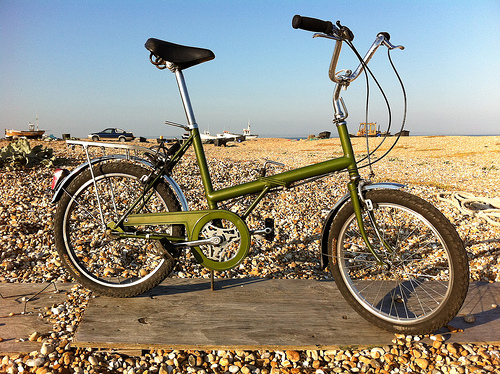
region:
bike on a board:
[51, 13, 461, 337]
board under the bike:
[68, 264, 479, 372]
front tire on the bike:
[308, 178, 467, 331]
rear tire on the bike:
[31, 158, 192, 288]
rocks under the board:
[138, 352, 225, 372]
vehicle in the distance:
[88, 122, 136, 142]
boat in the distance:
[3, 119, 49, 142]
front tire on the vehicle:
[88, 134, 100, 144]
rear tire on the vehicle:
[117, 135, 130, 142]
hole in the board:
[135, 311, 157, 328]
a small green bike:
[71, 26, 474, 320]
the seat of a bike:
[140, 37, 210, 82]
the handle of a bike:
[285, 7, 342, 42]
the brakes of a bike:
[366, 36, 414, 58]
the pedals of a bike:
[156, 231, 186, 266]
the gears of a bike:
[206, 217, 256, 268]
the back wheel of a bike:
[43, 146, 175, 281]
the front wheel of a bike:
[327, 195, 475, 330]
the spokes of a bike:
[390, 278, 442, 319]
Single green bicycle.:
[26, 10, 478, 346]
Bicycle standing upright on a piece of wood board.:
[42, 6, 477, 343]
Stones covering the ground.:
[57, 341, 479, 370]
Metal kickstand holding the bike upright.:
[195, 255, 230, 295]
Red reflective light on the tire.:
[40, 164, 82, 196]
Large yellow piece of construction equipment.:
[352, 116, 382, 137]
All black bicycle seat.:
[135, 29, 226, 71]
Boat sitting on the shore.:
[0, 112, 50, 149]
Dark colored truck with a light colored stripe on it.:
[83, 122, 140, 144]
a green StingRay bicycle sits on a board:
[102, 98, 384, 270]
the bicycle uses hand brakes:
[311, 32, 407, 170]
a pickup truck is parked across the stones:
[88, 123, 134, 142]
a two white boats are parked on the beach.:
[198, 125, 255, 146]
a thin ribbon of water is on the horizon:
[270, 131, 495, 136]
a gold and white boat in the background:
[0, 120, 41, 136]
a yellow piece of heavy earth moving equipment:
[350, 116, 380, 136]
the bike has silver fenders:
[53, 151, 191, 216]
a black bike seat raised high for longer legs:
[142, 31, 213, 72]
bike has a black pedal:
[237, 209, 299, 248]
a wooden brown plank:
[33, 286, 338, 364]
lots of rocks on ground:
[18, 145, 65, 321]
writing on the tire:
[323, 192, 478, 317]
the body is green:
[88, 99, 454, 298]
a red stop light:
[35, 153, 78, 220]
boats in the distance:
[200, 120, 277, 157]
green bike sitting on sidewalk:
[42, 17, 475, 338]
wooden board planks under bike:
[8, 260, 498, 357]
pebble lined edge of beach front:
[3, 129, 498, 365]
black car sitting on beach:
[87, 125, 134, 145]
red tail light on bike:
[45, 160, 64, 198]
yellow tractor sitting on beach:
[354, 119, 379, 136]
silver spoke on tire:
[388, 270, 430, 309]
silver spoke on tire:
[386, 277, 403, 317]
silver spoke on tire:
[343, 251, 373, 264]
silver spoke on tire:
[378, 202, 386, 252]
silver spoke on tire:
[105, 175, 122, 221]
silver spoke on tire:
[404, 233, 434, 260]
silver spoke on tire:
[342, 227, 371, 259]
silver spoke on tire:
[110, 235, 135, 285]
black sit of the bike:
[149, 36, 214, 63]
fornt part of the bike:
[326, 38, 449, 303]